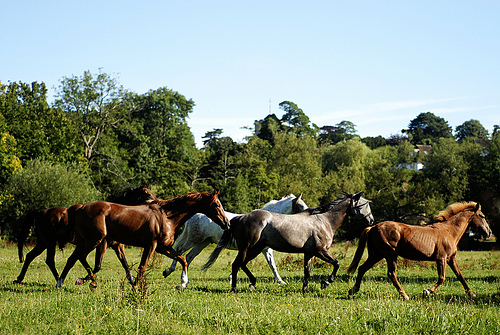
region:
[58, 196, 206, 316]
Brown horse in a field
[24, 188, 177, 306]
Brown horse running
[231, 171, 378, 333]
Dark brown horse running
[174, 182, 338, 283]
White horse running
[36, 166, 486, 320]
Horses in a field running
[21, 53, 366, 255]
Green trees by a field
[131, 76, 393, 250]
Green leaves on trees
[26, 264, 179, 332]
Green grass in a field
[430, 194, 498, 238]
Head on a horse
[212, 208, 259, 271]
Tail on a horse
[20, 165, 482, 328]
horses running on grass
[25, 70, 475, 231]
line of trees in back of horses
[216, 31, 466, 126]
blue sky with streaks of cloud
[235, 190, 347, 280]
silvery sheen on horse's body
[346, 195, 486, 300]
ribs showing on brown horse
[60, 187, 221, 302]
brown horse with white lower leg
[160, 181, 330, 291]
white horse in back of other horses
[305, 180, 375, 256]
horse wearing a head covering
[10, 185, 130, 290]
rear of horse behind same-color horse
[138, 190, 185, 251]
muscles bulging on front of horse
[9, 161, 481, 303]
there are five horses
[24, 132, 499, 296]
three of the horses are brown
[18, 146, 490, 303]
this is a herd of horses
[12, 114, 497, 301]
the animals are horses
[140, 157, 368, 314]
this horse is white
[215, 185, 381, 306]
this horse is grey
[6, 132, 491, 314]
the horses are walking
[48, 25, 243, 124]
the sky is clear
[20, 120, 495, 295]
horses are in a pasture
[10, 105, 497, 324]
the horses are free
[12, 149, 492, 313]
horses running in open field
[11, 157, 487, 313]
beautiful horses running in open field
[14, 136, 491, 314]
many horses running in open field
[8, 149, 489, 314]
several horses running in open field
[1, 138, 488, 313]
multiple horses running in open field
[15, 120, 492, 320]
plenty horses running in open field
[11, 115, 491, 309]
group of horses running in open field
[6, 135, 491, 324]
large group of horses running in open field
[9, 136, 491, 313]
variety of horses running in open field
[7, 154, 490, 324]
elegant horses running in open field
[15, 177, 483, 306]
several horses running in a field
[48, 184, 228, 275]
a dark brown horse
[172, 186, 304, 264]
a white horse with black spots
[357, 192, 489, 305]
a brown horse running in a field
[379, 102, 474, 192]
a white house with a red roof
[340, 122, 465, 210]
a house surrounded by trees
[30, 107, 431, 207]
a row of trees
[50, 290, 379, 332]
tall grass in a field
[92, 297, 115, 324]
yellow wildflowers in a field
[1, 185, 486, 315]
five horses running in a field